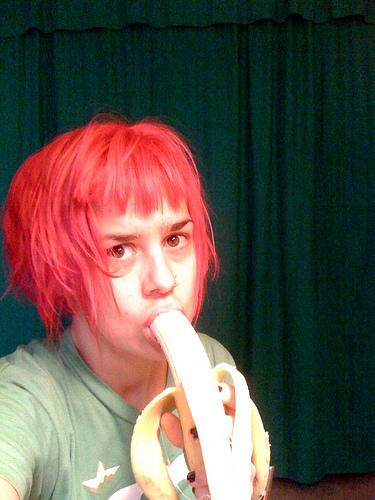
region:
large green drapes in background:
[219, 18, 371, 260]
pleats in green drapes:
[210, 48, 327, 156]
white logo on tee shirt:
[83, 455, 119, 491]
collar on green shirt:
[62, 358, 130, 420]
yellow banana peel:
[110, 381, 198, 496]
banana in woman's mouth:
[135, 295, 211, 342]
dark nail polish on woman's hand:
[178, 468, 203, 485]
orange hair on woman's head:
[36, 99, 242, 244]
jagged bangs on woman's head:
[68, 160, 227, 223]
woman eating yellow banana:
[17, 111, 326, 496]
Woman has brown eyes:
[7, 112, 230, 387]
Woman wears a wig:
[0, 108, 282, 495]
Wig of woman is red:
[0, 113, 225, 365]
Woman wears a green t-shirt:
[0, 112, 286, 496]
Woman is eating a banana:
[0, 117, 281, 496]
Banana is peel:
[117, 306, 283, 497]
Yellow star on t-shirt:
[71, 452, 121, 492]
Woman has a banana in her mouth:
[3, 109, 303, 497]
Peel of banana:
[122, 383, 190, 496]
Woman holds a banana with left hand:
[0, 115, 284, 499]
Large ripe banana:
[139, 308, 263, 493]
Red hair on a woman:
[0, 123, 129, 333]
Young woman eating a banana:
[8, 120, 220, 422]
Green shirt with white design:
[2, 334, 138, 494]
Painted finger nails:
[154, 408, 195, 494]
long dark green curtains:
[214, 1, 367, 473]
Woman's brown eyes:
[98, 226, 203, 262]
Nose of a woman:
[138, 241, 180, 301]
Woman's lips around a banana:
[121, 300, 204, 354]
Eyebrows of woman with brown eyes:
[96, 216, 208, 234]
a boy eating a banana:
[8, 112, 352, 497]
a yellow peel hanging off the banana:
[227, 367, 254, 488]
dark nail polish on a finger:
[182, 471, 199, 485]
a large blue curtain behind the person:
[273, 235, 357, 458]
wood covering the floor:
[296, 486, 345, 499]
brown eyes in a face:
[105, 233, 201, 256]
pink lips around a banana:
[149, 305, 182, 316]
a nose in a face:
[143, 259, 190, 291]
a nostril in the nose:
[148, 283, 162, 298]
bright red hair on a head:
[53, 131, 207, 223]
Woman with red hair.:
[17, 104, 251, 495]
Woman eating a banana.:
[0, 140, 330, 498]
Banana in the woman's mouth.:
[135, 276, 271, 497]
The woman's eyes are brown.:
[97, 212, 210, 267]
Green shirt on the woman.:
[0, 317, 292, 498]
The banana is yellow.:
[131, 284, 268, 498]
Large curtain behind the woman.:
[0, 2, 372, 477]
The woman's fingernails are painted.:
[174, 369, 220, 497]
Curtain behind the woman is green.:
[7, 7, 354, 484]